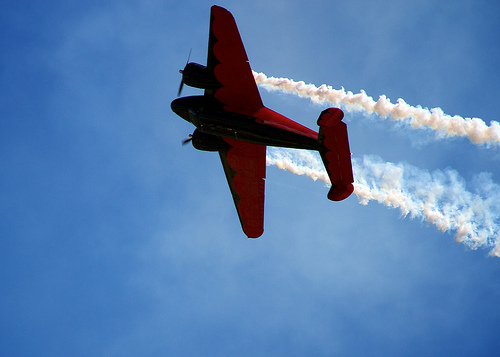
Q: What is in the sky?
A: The red plane is in the sky.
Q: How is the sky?
A: The sky is blue with light white clouds.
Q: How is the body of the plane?
A: THe body of the plane is red and black.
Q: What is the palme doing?
A: The plane is leaving a trail of white smoke in the sky.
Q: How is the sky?
A: The sky is blue and clear.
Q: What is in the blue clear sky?
A: The front of the red plane.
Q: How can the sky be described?
A: Blue and clear.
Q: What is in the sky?
A: A red plane.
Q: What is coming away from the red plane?
A: White smoke.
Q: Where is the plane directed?
A: To the right.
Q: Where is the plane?
A: In the middle of the image.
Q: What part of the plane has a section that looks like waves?
A: The wings.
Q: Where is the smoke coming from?
A: A red and black airplane.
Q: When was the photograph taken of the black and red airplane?
A: Thursday afternoon.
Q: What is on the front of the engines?
A: Propellers.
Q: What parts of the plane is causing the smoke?
A: Engines.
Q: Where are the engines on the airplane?
A: Wings.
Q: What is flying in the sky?
A: Airplane.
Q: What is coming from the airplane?
A: Smoke.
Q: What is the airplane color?
A: Red.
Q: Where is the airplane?
A: In the sky.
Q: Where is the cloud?
A: In the sky.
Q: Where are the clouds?
A: In the sky.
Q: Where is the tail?
A: On the plane.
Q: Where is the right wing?
A: On the plane.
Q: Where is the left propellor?
A: On the plane.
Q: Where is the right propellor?
A: On the plane.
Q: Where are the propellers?
A: On the plane.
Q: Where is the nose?
A: On the plane.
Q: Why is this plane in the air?
A: To fly.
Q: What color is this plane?
A: Orange and black.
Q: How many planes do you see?
A: Only one.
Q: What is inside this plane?
A: A engine.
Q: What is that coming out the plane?
A: White clouds of smoke.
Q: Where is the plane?
A: In the sky.